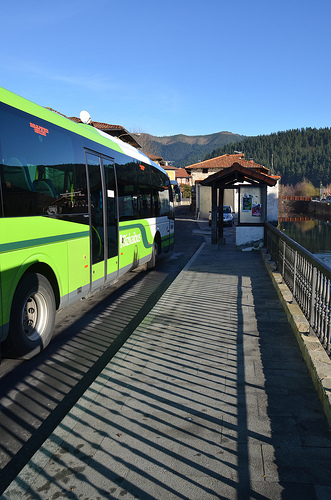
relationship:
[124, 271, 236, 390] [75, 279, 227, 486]
shadows on ground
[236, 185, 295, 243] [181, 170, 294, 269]
flyers on stop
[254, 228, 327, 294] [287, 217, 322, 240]
railng by water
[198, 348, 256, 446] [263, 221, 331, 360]
shadow of railng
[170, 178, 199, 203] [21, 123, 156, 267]
mirror on bus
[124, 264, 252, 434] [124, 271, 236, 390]
sidewalk has shadows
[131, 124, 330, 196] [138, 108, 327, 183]
hill in background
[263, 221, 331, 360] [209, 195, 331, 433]
railng on bridge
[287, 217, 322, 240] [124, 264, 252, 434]
water on sidewalk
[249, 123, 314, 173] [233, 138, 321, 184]
trees on hill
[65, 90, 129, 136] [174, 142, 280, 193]
dish on roof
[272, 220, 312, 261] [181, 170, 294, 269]
rail at stop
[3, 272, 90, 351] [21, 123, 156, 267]
tire on bus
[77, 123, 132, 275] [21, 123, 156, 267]
doors on bus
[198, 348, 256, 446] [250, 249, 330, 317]
shadow of rails